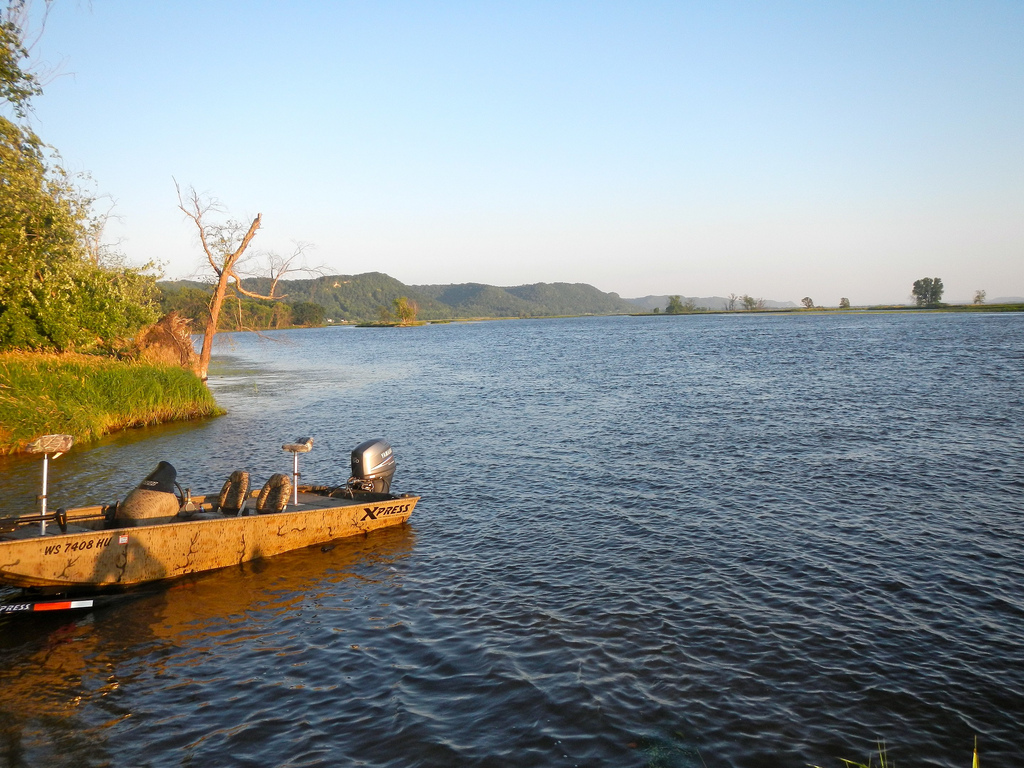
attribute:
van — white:
[717, 733, 901, 740]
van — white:
[605, 733, 940, 755]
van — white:
[767, 739, 934, 740]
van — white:
[680, 716, 858, 725]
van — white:
[583, 733, 903, 760]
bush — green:
[10, 117, 153, 357]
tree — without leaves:
[160, 180, 329, 388]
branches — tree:
[185, 169, 298, 306]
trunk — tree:
[129, 301, 212, 377]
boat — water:
[6, 409, 430, 593]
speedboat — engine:
[8, 415, 426, 584]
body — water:
[522, 361, 946, 681]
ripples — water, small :
[475, 556, 879, 716]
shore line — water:
[24, 370, 212, 451]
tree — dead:
[2, 7, 171, 360]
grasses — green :
[4, 348, 179, 428]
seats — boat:
[214, 463, 305, 522]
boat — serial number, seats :
[11, 422, 416, 602]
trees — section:
[13, 11, 173, 361]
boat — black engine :
[17, 415, 426, 621]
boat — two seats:
[214, 459, 299, 505]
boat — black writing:
[36, 495, 426, 580]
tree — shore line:
[159, 186, 268, 400]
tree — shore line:
[177, 176, 283, 418]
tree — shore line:
[166, 184, 300, 399]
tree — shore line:
[179, 182, 281, 377]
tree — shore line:
[172, 173, 289, 409]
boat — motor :
[6, 392, 426, 645]